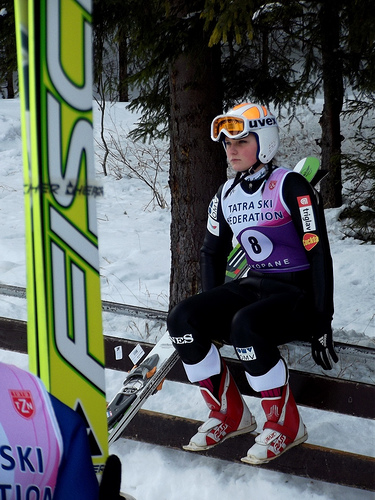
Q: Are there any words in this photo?
A: Yes, there are words.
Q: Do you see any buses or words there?
A: Yes, there are words.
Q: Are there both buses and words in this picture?
A: No, there are words but no buses.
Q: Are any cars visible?
A: No, there are no cars.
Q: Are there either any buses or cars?
A: No, there are no cars or buses.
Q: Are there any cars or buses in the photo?
A: No, there are no cars or buses.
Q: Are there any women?
A: Yes, there is a woman.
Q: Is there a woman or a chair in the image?
A: Yes, there is a woman.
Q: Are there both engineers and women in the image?
A: No, there is a woman but no engineers.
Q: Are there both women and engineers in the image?
A: No, there is a woman but no engineers.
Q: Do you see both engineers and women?
A: No, there is a woman but no engineers.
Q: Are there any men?
A: No, there are no men.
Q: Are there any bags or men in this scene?
A: No, there are no men or bags.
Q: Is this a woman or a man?
A: This is a woman.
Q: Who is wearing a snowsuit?
A: The woman is wearing a snowsuit.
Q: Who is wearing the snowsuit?
A: The woman is wearing a snowsuit.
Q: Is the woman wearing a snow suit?
A: Yes, the woman is wearing a snow suit.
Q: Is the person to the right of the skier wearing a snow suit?
A: Yes, the woman is wearing a snow suit.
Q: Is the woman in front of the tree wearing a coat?
A: No, the woman is wearing a snow suit.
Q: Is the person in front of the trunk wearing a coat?
A: No, the woman is wearing a snow suit.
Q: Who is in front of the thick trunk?
A: The woman is in front of the trunk.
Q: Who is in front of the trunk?
A: The woman is in front of the trunk.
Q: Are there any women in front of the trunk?
A: Yes, there is a woman in front of the trunk.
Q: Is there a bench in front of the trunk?
A: No, there is a woman in front of the trunk.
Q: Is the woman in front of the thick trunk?
A: Yes, the woman is in front of the trunk.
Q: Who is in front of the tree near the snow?
A: The woman is in front of the tree.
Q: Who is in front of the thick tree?
A: The woman is in front of the tree.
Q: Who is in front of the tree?
A: The woman is in front of the tree.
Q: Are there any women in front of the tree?
A: Yes, there is a woman in front of the tree.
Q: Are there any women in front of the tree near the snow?
A: Yes, there is a woman in front of the tree.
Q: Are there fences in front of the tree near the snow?
A: No, there is a woman in front of the tree.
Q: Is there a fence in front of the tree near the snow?
A: No, there is a woman in front of the tree.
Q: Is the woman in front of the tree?
A: Yes, the woman is in front of the tree.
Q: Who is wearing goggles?
A: The woman is wearing goggles.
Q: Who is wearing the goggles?
A: The woman is wearing goggles.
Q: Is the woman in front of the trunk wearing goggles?
A: Yes, the woman is wearing goggles.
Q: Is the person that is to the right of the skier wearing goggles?
A: Yes, the woman is wearing goggles.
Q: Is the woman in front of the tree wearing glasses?
A: No, the woman is wearing goggles.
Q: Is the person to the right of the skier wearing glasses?
A: No, the woman is wearing goggles.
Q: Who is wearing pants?
A: The woman is wearing pants.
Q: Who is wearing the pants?
A: The woman is wearing pants.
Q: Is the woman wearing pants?
A: Yes, the woman is wearing pants.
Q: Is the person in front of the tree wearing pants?
A: Yes, the woman is wearing pants.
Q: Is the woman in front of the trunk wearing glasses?
A: No, the woman is wearing pants.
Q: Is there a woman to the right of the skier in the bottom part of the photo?
A: Yes, there is a woman to the right of the skier.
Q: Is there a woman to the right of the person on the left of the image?
A: Yes, there is a woman to the right of the skier.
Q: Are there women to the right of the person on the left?
A: Yes, there is a woman to the right of the skier.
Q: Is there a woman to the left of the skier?
A: No, the woman is to the right of the skier.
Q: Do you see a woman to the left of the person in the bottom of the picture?
A: No, the woman is to the right of the skier.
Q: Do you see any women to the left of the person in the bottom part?
A: No, the woman is to the right of the skier.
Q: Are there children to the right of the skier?
A: No, there is a woman to the right of the skier.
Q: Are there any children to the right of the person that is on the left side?
A: No, there is a woman to the right of the skier.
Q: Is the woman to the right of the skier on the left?
A: Yes, the woman is to the right of the skier.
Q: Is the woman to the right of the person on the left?
A: Yes, the woman is to the right of the skier.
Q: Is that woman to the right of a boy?
A: No, the woman is to the right of the skier.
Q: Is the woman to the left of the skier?
A: No, the woman is to the right of the skier.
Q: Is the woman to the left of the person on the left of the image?
A: No, the woman is to the right of the skier.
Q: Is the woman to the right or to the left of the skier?
A: The woman is to the right of the skier.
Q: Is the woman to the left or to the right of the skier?
A: The woman is to the right of the skier.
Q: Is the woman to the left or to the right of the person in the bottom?
A: The woman is to the right of the skier.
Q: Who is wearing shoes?
A: The woman is wearing shoes.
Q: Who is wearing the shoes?
A: The woman is wearing shoes.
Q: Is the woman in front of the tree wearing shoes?
A: Yes, the woman is wearing shoes.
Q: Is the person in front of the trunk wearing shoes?
A: Yes, the woman is wearing shoes.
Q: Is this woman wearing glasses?
A: No, the woman is wearing shoes.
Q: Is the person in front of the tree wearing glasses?
A: No, the woman is wearing shoes.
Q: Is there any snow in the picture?
A: Yes, there is snow.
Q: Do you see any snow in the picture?
A: Yes, there is snow.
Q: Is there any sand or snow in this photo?
A: Yes, there is snow.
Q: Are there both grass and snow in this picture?
A: No, there is snow but no grass.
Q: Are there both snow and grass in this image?
A: No, there is snow but no grass.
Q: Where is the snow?
A: The snow is on the ground.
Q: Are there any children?
A: No, there are no children.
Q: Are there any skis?
A: Yes, there are skis.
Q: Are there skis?
A: Yes, there are skis.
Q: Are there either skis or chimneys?
A: Yes, there are skis.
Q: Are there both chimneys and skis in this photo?
A: No, there are skis but no chimneys.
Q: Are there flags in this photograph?
A: No, there are no flags.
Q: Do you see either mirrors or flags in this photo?
A: No, there are no flags or mirrors.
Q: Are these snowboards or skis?
A: These are skis.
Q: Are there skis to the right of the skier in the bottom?
A: Yes, there are skis to the right of the skier.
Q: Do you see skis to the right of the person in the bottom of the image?
A: Yes, there are skis to the right of the skier.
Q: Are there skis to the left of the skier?
A: No, the skis are to the right of the skier.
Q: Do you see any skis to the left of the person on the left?
A: No, the skis are to the right of the skier.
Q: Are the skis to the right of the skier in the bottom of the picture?
A: Yes, the skis are to the right of the skier.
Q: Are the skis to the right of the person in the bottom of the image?
A: Yes, the skis are to the right of the skier.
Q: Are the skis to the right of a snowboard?
A: No, the skis are to the right of the skier.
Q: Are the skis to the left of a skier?
A: No, the skis are to the right of a skier.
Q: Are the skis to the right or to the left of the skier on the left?
A: The skis are to the right of the skier.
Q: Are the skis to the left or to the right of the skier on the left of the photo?
A: The skis are to the right of the skier.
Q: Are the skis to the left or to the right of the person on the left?
A: The skis are to the right of the skier.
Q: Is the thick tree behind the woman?
A: Yes, the tree is behind the woman.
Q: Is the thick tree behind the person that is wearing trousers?
A: Yes, the tree is behind the woman.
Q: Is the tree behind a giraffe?
A: No, the tree is behind the woman.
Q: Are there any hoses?
A: No, there are no hoses.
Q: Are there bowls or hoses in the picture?
A: No, there are no hoses or bowls.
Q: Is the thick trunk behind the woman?
A: Yes, the trunk is behind the woman.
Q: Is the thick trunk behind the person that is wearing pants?
A: Yes, the trunk is behind the woman.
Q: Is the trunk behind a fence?
A: No, the trunk is behind the woman.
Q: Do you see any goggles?
A: Yes, there are goggles.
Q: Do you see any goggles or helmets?
A: Yes, there are goggles.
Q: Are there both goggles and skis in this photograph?
A: Yes, there are both goggles and skis.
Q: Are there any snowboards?
A: No, there are no snowboards.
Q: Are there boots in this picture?
A: Yes, there are boots.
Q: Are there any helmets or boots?
A: Yes, there are boots.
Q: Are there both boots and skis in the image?
A: Yes, there are both boots and skis.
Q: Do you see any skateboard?
A: No, there are no skateboards.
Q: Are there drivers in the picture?
A: No, there are no drivers.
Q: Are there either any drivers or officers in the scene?
A: No, there are no drivers or officers.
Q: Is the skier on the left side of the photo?
A: Yes, the skier is on the left of the image.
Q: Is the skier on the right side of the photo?
A: No, the skier is on the left of the image.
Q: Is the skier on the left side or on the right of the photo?
A: The skier is on the left of the image.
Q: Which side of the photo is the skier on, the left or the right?
A: The skier is on the left of the image.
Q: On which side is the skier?
A: The skier is on the left of the image.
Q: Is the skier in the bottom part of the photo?
A: Yes, the skier is in the bottom of the image.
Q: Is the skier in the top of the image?
A: No, the skier is in the bottom of the image.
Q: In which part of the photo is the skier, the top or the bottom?
A: The skier is in the bottom of the image.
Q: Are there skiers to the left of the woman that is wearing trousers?
A: Yes, there is a skier to the left of the woman.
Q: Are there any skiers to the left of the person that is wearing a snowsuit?
A: Yes, there is a skier to the left of the woman.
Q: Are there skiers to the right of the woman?
A: No, the skier is to the left of the woman.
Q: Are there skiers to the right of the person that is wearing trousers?
A: No, the skier is to the left of the woman.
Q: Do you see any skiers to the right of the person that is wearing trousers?
A: No, the skier is to the left of the woman.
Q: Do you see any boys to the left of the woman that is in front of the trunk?
A: No, there is a skier to the left of the woman.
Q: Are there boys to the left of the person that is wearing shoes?
A: No, there is a skier to the left of the woman.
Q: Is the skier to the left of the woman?
A: Yes, the skier is to the left of the woman.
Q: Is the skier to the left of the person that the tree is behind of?
A: Yes, the skier is to the left of the woman.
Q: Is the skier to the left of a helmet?
A: No, the skier is to the left of the woman.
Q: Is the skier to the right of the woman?
A: No, the skier is to the left of the woman.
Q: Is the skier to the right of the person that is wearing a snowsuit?
A: No, the skier is to the left of the woman.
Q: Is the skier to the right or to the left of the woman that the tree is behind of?
A: The skier is to the left of the woman.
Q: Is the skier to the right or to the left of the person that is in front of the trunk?
A: The skier is to the left of the woman.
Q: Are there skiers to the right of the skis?
A: No, the skier is to the left of the skis.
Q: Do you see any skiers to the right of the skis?
A: No, the skier is to the left of the skis.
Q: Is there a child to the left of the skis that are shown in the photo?
A: No, there is a skier to the left of the skis.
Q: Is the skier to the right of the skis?
A: No, the skier is to the left of the skis.